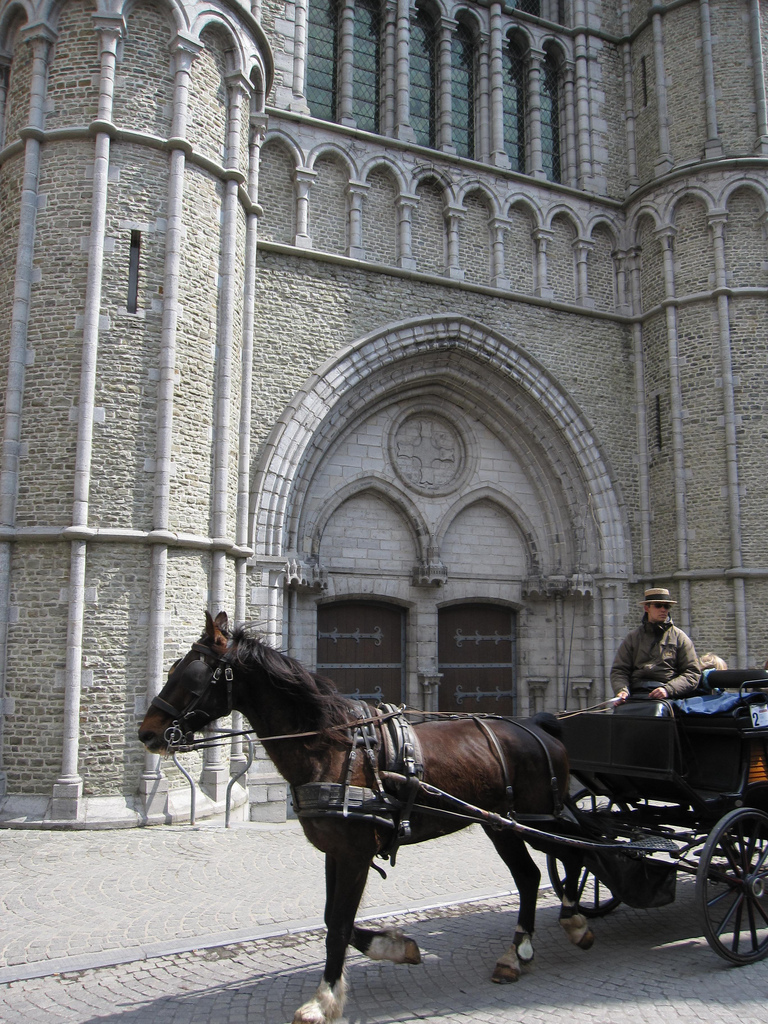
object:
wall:
[243, 236, 652, 809]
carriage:
[551, 665, 768, 969]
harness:
[291, 698, 426, 879]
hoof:
[395, 936, 421, 966]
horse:
[139, 607, 597, 1023]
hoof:
[293, 988, 336, 1024]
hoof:
[492, 955, 522, 983]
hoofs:
[289, 903, 596, 1023]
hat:
[638, 588, 677, 605]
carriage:
[384, 666, 768, 965]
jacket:
[608, 610, 700, 708]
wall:
[86, 132, 175, 532]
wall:
[74, 532, 153, 805]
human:
[608, 588, 701, 708]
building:
[0, 0, 766, 830]